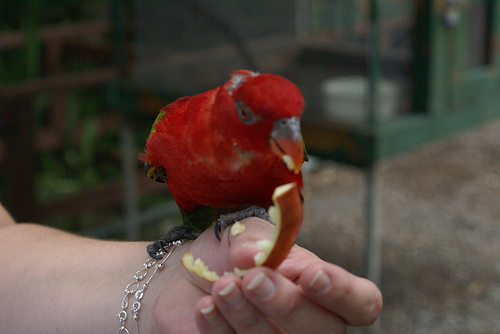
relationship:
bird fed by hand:
[140, 69, 305, 254] [151, 213, 381, 333]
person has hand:
[2, 203, 183, 333] [151, 213, 381, 333]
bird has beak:
[140, 69, 305, 254] [268, 118, 305, 173]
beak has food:
[268, 118, 305, 173] [284, 153, 299, 173]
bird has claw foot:
[140, 69, 305, 254] [144, 211, 201, 261]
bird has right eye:
[140, 69, 305, 254] [237, 106, 251, 122]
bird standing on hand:
[140, 69, 305, 254] [151, 213, 381, 333]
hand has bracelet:
[151, 213, 381, 333] [115, 240, 182, 327]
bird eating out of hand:
[140, 69, 305, 254] [151, 213, 381, 333]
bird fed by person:
[140, 69, 305, 254] [2, 203, 183, 333]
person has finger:
[2, 203, 183, 333] [303, 261, 385, 323]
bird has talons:
[140, 69, 305, 254] [213, 205, 274, 238]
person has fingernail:
[2, 203, 183, 333] [246, 272, 274, 300]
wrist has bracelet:
[100, 235, 196, 334] [115, 240, 182, 327]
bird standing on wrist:
[140, 69, 305, 254] [100, 235, 196, 334]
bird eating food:
[140, 69, 305, 254] [284, 153, 299, 173]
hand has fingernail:
[151, 213, 381, 333] [246, 272, 274, 300]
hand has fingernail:
[151, 213, 381, 333] [218, 282, 241, 309]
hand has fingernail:
[151, 213, 381, 333] [205, 306, 219, 329]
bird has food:
[140, 69, 305, 254] [284, 153, 299, 173]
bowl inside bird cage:
[325, 77, 395, 122] [117, 0, 497, 313]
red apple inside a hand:
[181, 182, 303, 295] [151, 213, 381, 333]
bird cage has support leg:
[117, 0, 497, 313] [362, 165, 389, 331]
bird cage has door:
[117, 0, 497, 313] [424, 3, 498, 115]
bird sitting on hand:
[140, 69, 305, 254] [151, 213, 381, 333]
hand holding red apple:
[151, 213, 381, 333] [181, 182, 303, 295]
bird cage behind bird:
[117, 0, 497, 313] [140, 69, 305, 254]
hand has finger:
[151, 213, 381, 333] [303, 261, 385, 323]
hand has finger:
[151, 213, 381, 333] [241, 268, 345, 333]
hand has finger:
[151, 213, 381, 333] [212, 272, 274, 333]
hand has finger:
[151, 213, 381, 333] [194, 295, 232, 333]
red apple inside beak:
[181, 182, 303, 295] [268, 118, 305, 173]